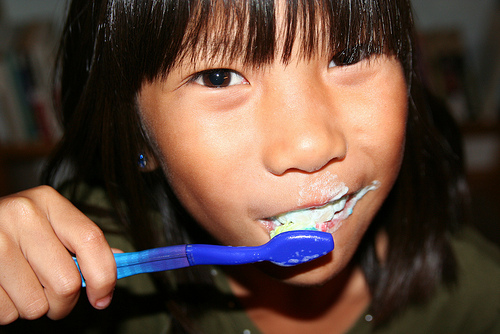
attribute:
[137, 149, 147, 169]
earring — blue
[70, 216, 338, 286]
toothbrush — blue, dark blue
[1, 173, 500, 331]
shirt — green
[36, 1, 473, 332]
hair — dark, thin, straight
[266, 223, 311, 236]
toothbrush bristles — yellow